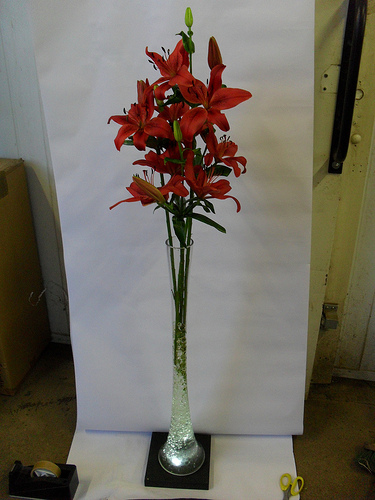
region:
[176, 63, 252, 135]
red colored lily flower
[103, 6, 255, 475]
bunch of red lilies.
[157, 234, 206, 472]
glass base on platform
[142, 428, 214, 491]
black base on floor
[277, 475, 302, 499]
yellow scissors on floor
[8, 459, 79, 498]
roll of tape in dispenser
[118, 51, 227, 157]
Red sepals on the flowers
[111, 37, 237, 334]
A flower in the vase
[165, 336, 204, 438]
A glass vase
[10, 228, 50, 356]
A cabinet in the background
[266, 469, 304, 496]
Scissors on the floor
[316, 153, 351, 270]
a wall in the background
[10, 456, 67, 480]
A cellotape on the floor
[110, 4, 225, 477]
Flowers in flower vase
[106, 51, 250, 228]
Bright red flowers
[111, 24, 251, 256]
bright red lily flowers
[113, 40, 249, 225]
bright vivid red lily flowers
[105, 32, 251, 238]
vivid crimson flowers in a vase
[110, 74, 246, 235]
vivid red flowers in vase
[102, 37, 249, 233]
vivid sanguine flowers in vase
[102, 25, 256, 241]
bright blood red flowers in vase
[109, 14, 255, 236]
blood red lilies in a vase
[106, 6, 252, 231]
Orange flowers in a vase.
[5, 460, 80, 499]
Scotch tape holder.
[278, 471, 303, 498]
Yellow and grey scissors.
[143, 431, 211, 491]
Black base on a vase.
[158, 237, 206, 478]
Very long glass vase.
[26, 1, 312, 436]
A very long white piece of paper.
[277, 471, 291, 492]
Smaller yellow finger hole on the scissors.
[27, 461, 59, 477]
Roll of tape.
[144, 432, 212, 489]
Black base under a vase.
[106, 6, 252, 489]
Red flowers displayed in a vase.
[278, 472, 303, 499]
Yellow scissors lying on the ground.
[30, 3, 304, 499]
A white drop cloth used for photography.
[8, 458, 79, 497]
An empty tape dispenser.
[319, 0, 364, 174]
A long, black handle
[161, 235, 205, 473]
A clear glass vase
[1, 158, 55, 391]
A closed, brown moving box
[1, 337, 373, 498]
Brown stained carpet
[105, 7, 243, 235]
Bright red, vibrant, and living flowers.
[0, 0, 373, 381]
White panel walls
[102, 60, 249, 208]
Red flowers on the vase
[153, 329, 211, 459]
A vase on the floor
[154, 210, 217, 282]
Black sepals of the flowers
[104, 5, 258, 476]
red flowers in vase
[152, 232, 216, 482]
clear glass flower vase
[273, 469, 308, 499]
scissors with yellow handle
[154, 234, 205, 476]
a clear glass vase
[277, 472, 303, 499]
a pair of scissors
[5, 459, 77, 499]
a black tape dispenser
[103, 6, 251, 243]
a flower bouquet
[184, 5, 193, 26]
an unopened flower bud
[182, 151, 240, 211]
a red Tiger Lily flower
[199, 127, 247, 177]
a red Tiger Lily flower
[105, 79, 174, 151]
a red Tiger Lily flower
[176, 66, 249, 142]
a red Tiger Lily flower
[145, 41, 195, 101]
a red Tiger Lily flower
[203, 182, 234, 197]
red pedal on the tall flower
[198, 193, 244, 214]
red pedal on the tall flower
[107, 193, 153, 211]
red pedal on the tall flower